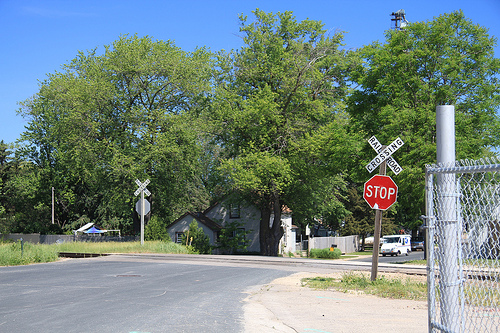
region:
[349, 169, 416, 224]
red and white stop sign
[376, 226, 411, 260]
large white postal truck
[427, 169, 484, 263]
silver chain link fence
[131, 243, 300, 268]
train tracks in middle of street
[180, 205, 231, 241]
slanted gray house roof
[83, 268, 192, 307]
gray color on the street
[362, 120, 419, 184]
white railroad crossing sign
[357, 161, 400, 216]
a red stop sign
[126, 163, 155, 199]
white railroad crossing sign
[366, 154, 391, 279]
a sign on pole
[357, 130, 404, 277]
the pole is metal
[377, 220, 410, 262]
the van is white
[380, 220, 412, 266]
the van is mail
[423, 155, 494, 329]
the fence is metal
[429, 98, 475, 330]
the pole is metal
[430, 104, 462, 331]
the pole is gray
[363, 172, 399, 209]
Red stop sign with white letters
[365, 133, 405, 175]
Crisscrossed white and black railroad crossing sign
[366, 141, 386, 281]
Brown wooden pole holding two signs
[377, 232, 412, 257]
White, small mail truck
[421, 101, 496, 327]
Gray chained link fence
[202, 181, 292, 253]
White and brown house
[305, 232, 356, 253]
White fence beside a house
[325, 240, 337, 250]
Black mailbox beside a house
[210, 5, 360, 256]
Large greened out tree beside a house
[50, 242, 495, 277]
Railroad track crossing road nearby a house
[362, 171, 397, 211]
the sign is red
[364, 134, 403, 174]
crossing sign is white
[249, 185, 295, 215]
the roof is brown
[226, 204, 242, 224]
windows on the house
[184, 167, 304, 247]
house behind the tree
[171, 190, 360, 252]
fence in front of the house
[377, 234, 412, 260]
mail truck is white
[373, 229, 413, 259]
mail truck on the road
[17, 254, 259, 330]
the road is gray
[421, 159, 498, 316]
the fence is silver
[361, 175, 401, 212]
red stop sign on a pole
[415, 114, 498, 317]
grey chain link fence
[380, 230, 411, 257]
white mail truck parked down the road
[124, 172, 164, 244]
railroad crossing sign across the tracks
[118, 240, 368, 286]
railroad tracks going over the road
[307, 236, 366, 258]
white fence next to a house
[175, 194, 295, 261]
small white house among trees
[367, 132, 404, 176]
railroad crossing sign in an x shape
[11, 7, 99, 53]
very clear and blue sky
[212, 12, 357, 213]
large green leafy tree across the road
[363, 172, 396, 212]
a red and white traffic sign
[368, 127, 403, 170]
a black and white traffic sign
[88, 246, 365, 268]
a set of train tracks